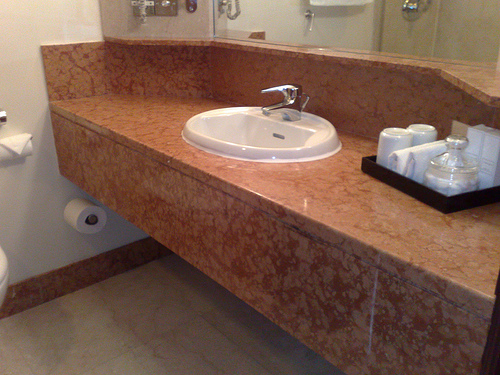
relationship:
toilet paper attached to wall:
[0, 132, 35, 163] [1, 0, 149, 285]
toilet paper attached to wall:
[63, 197, 108, 237] [1, 0, 149, 285]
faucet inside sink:
[259, 84, 311, 123] [182, 106, 342, 165]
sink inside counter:
[182, 106, 342, 165] [49, 97, 499, 324]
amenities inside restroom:
[361, 118, 499, 214] [2, 0, 499, 374]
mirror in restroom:
[99, 1, 499, 70] [2, 0, 499, 374]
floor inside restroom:
[1, 252, 345, 375] [2, 0, 499, 374]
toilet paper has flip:
[0, 132, 35, 163] [2, 134, 32, 156]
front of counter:
[48, 109, 499, 374] [49, 97, 499, 324]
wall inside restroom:
[1, 0, 149, 285] [2, 0, 499, 374]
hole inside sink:
[272, 132, 284, 141] [182, 106, 342, 165]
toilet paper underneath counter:
[63, 197, 108, 237] [49, 97, 499, 324]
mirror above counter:
[99, 1, 499, 70] [49, 97, 499, 324]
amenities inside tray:
[361, 118, 499, 214] [360, 154, 499, 213]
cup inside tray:
[406, 123, 437, 147] [360, 154, 499, 213]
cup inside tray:
[376, 128, 412, 169] [360, 154, 499, 213]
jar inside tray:
[423, 134, 482, 198] [360, 154, 499, 213]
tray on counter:
[360, 154, 499, 213] [49, 97, 499, 324]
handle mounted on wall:
[87, 215, 96, 223] [1, 0, 149, 285]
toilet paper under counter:
[0, 132, 35, 163] [49, 97, 499, 324]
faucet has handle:
[259, 84, 311, 123] [260, 83, 301, 97]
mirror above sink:
[99, 1, 499, 70] [182, 106, 342, 165]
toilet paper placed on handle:
[63, 197, 108, 237] [87, 215, 96, 223]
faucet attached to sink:
[259, 84, 311, 123] [182, 106, 342, 165]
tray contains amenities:
[360, 154, 499, 213] [361, 118, 499, 214]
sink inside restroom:
[182, 106, 342, 165] [2, 0, 499, 374]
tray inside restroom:
[360, 154, 499, 213] [2, 0, 499, 374]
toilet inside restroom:
[1, 249, 12, 307] [2, 0, 499, 374]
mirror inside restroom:
[99, 1, 499, 70] [2, 0, 499, 374]